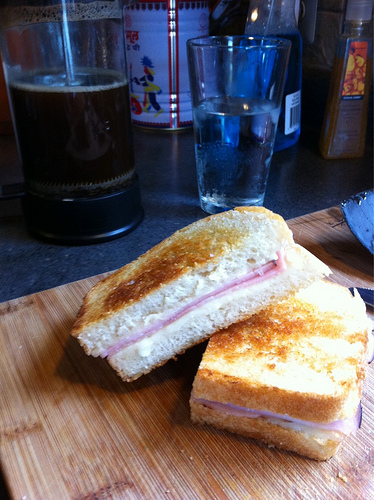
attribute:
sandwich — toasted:
[70, 202, 305, 386]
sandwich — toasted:
[190, 280, 372, 461]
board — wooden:
[0, 202, 374, 499]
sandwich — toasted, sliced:
[66, 203, 370, 460]